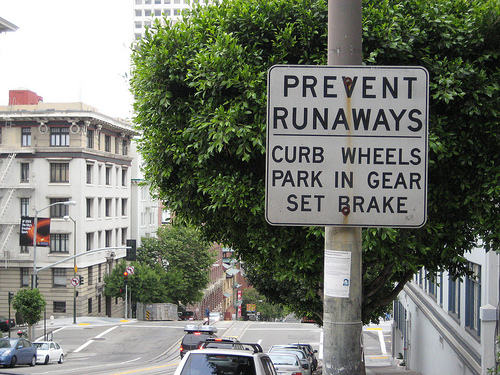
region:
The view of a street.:
[0, 0, 495, 372]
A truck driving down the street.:
[175, 320, 215, 355]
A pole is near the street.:
[315, 0, 370, 370]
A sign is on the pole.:
[260, 60, 425, 225]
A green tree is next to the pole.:
[125, 0, 490, 315]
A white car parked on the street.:
[30, 338, 65, 364]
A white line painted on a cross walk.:
[371, 322, 386, 352]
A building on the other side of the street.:
[0, 85, 135, 321]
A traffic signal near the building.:
[117, 265, 132, 316]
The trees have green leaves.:
[100, 210, 211, 320]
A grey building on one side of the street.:
[0, 87, 135, 320]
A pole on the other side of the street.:
[317, 0, 372, 371]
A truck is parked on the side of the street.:
[170, 335, 275, 370]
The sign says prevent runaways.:
[266, 65, 426, 135]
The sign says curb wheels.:
[265, 140, 425, 165]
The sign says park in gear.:
[271, 165, 417, 191]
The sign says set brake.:
[285, 188, 416, 214]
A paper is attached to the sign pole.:
[322, 245, 352, 300]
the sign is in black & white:
[255, 57, 440, 237]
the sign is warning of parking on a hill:
[257, 55, 437, 240]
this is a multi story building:
[4, 102, 134, 315]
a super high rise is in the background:
[132, 0, 221, 71]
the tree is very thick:
[187, 27, 262, 178]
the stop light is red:
[119, 265, 136, 311]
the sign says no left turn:
[67, 274, 82, 290]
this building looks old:
[0, 91, 133, 317]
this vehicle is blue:
[1, 332, 36, 371]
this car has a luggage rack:
[196, 338, 260, 359]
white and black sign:
[265, 65, 427, 226]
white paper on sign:
[325, 248, 351, 298]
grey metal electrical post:
[323, 2, 363, 374]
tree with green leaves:
[133, 1, 497, 323]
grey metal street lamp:
[33, 200, 76, 300]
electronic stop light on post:
[121, 269, 129, 316]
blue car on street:
[3, 336, 36, 367]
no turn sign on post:
[71, 274, 80, 288]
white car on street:
[32, 340, 65, 365]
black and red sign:
[18, 215, 51, 245]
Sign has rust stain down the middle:
[339, 72, 364, 224]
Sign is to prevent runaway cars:
[265, 65, 426, 228]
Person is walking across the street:
[200, 302, 212, 326]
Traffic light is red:
[119, 270, 129, 284]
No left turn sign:
[68, 276, 81, 287]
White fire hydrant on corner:
[48, 312, 58, 327]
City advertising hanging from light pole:
[19, 213, 53, 245]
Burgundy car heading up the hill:
[173, 307, 203, 322]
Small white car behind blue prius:
[33, 337, 66, 364]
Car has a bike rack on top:
[197, 340, 264, 355]